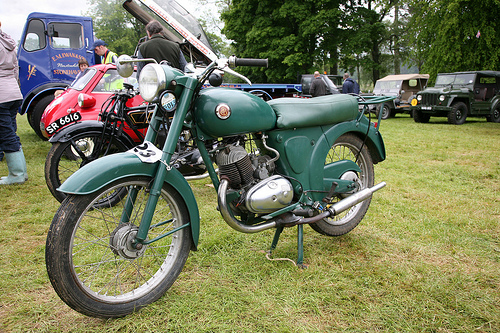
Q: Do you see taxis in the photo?
A: Yes, there is a taxi.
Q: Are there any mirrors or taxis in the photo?
A: Yes, there is a taxi.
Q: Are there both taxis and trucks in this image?
A: Yes, there are both a taxi and trucks.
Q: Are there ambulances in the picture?
A: No, there are no ambulances.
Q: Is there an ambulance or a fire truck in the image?
A: No, there are no ambulances or fire trucks.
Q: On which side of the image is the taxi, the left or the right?
A: The taxi is on the right of the image.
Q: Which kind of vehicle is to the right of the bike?
A: The vehicle is a taxi.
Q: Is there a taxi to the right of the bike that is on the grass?
A: Yes, there is a taxi to the right of the bike.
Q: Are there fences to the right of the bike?
A: No, there is a taxi to the right of the bike.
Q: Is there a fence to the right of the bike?
A: No, there is a taxi to the right of the bike.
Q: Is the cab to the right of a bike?
A: Yes, the cab is to the right of a bike.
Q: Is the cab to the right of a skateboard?
A: No, the cab is to the right of a bike.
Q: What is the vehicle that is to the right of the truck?
A: The vehicle is a taxi.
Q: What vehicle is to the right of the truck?
A: The vehicle is a taxi.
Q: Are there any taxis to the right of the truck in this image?
A: Yes, there is a taxi to the right of the truck.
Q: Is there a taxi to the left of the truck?
A: No, the taxi is to the right of the truck.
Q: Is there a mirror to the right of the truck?
A: No, there is a taxi to the right of the truck.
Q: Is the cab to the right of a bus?
A: No, the cab is to the right of the truck.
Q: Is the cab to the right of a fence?
A: No, the cab is to the right of the jeep.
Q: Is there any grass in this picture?
A: Yes, there is grass.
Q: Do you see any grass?
A: Yes, there is grass.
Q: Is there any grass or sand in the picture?
A: Yes, there is grass.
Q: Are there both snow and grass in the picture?
A: No, there is grass but no snow.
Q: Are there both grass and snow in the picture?
A: No, there is grass but no snow.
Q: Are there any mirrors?
A: No, there are no mirrors.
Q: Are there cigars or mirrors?
A: No, there are no mirrors or cigars.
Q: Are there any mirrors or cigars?
A: No, there are no mirrors or cigars.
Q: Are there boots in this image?
A: Yes, there are boots.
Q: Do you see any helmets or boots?
A: Yes, there are boots.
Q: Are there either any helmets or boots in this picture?
A: Yes, there are boots.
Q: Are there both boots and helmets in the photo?
A: No, there are boots but no helmets.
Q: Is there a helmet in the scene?
A: No, there are no helmets.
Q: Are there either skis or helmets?
A: No, there are no helmets or skis.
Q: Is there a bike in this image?
A: Yes, there is a bike.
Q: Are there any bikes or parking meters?
A: Yes, there is a bike.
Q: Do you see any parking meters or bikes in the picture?
A: Yes, there is a bike.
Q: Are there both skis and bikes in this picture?
A: No, there is a bike but no skis.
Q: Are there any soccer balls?
A: No, there are no soccer balls.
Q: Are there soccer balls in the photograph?
A: No, there are no soccer balls.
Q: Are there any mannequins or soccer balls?
A: No, there are no soccer balls or mannequins.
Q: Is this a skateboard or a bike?
A: This is a bike.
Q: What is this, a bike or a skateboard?
A: This is a bike.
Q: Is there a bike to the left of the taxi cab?
A: Yes, there is a bike to the left of the taxi cab.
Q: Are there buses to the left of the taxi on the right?
A: No, there is a bike to the left of the cab.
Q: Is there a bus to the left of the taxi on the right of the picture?
A: No, there is a bike to the left of the cab.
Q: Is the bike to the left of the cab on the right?
A: Yes, the bike is to the left of the cab.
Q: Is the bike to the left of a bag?
A: No, the bike is to the left of the cab.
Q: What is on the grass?
A: The bike is on the grass.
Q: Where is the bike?
A: The bike is on the grass.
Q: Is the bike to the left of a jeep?
A: Yes, the bike is to the left of a jeep.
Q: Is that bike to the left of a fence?
A: No, the bike is to the left of a jeep.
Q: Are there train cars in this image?
A: No, there are no train cars.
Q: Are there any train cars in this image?
A: No, there are no train cars.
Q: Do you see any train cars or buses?
A: No, there are no train cars or buses.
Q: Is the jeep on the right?
A: Yes, the jeep is on the right of the image.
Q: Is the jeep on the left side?
A: No, the jeep is on the right of the image.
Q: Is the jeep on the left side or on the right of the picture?
A: The jeep is on the right of the image.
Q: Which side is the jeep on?
A: The jeep is on the right of the image.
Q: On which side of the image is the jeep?
A: The jeep is on the right of the image.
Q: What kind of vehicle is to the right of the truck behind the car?
A: The vehicle is a jeep.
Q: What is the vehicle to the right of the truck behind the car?
A: The vehicle is a jeep.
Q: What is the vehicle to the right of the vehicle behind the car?
A: The vehicle is a jeep.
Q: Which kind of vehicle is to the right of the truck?
A: The vehicle is a jeep.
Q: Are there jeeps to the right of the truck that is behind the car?
A: Yes, there is a jeep to the right of the truck.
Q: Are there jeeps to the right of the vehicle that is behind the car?
A: Yes, there is a jeep to the right of the truck.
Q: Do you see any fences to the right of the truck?
A: No, there is a jeep to the right of the truck.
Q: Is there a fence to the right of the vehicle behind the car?
A: No, there is a jeep to the right of the truck.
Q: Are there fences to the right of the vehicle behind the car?
A: No, there is a jeep to the right of the truck.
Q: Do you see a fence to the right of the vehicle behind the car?
A: No, there is a jeep to the right of the truck.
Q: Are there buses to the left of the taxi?
A: No, there is a jeep to the left of the taxi.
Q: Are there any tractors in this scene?
A: No, there are no tractors.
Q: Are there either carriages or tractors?
A: No, there are no tractors or carriages.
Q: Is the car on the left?
A: Yes, the car is on the left of the image.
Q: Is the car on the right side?
A: No, the car is on the left of the image.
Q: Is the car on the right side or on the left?
A: The car is on the left of the image.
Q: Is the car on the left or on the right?
A: The car is on the left of the image.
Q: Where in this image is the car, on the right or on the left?
A: The car is on the left of the image.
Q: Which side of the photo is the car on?
A: The car is on the left of the image.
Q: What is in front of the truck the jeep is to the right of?
A: The car is in front of the truck.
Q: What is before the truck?
A: The car is in front of the truck.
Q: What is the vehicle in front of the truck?
A: The vehicle is a car.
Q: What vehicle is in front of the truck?
A: The vehicle is a car.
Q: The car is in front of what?
A: The car is in front of the truck.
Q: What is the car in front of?
A: The car is in front of the truck.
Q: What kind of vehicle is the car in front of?
A: The car is in front of the truck.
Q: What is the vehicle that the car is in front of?
A: The vehicle is a truck.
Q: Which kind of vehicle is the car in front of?
A: The car is in front of the truck.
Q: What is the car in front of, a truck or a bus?
A: The car is in front of a truck.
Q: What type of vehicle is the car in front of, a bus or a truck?
A: The car is in front of a truck.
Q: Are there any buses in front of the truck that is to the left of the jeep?
A: No, there is a car in front of the truck.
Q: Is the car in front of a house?
A: No, the car is in front of the truck.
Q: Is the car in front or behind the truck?
A: The car is in front of the truck.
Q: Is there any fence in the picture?
A: No, there are no fences.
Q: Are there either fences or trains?
A: No, there are no fences or trains.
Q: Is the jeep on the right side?
A: Yes, the jeep is on the right of the image.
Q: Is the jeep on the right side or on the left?
A: The jeep is on the right of the image.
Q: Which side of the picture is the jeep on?
A: The jeep is on the right of the image.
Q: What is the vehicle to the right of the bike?
A: The vehicle is a jeep.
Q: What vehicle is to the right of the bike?
A: The vehicle is a jeep.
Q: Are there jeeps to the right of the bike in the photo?
A: Yes, there is a jeep to the right of the bike.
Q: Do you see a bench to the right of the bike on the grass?
A: No, there is a jeep to the right of the bike.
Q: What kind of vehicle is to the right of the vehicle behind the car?
A: The vehicle is a jeep.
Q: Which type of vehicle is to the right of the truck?
A: The vehicle is a jeep.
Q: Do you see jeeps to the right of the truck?
A: Yes, there is a jeep to the right of the truck.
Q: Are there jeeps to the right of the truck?
A: Yes, there is a jeep to the right of the truck.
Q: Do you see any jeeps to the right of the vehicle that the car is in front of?
A: Yes, there is a jeep to the right of the truck.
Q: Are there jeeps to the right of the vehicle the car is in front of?
A: Yes, there is a jeep to the right of the truck.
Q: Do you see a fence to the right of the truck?
A: No, there is a jeep to the right of the truck.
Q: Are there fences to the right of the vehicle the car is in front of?
A: No, there is a jeep to the right of the truck.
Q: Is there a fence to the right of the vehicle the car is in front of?
A: No, there is a jeep to the right of the truck.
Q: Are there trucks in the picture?
A: Yes, there is a truck.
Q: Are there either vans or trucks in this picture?
A: Yes, there is a truck.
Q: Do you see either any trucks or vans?
A: Yes, there is a truck.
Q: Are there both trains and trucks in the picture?
A: No, there is a truck but no trains.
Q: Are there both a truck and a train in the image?
A: No, there is a truck but no trains.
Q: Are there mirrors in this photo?
A: No, there are no mirrors.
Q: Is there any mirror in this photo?
A: No, there are no mirrors.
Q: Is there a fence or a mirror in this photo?
A: No, there are no mirrors or fences.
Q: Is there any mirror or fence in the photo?
A: No, there are no mirrors or fences.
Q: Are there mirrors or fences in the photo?
A: No, there are no mirrors or fences.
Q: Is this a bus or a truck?
A: This is a truck.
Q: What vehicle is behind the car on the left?
A: The vehicle is a truck.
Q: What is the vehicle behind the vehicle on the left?
A: The vehicle is a truck.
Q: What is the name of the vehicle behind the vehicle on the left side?
A: The vehicle is a truck.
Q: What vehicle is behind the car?
A: The vehicle is a truck.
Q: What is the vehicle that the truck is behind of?
A: The vehicle is a car.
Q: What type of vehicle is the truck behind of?
A: The truck is behind the car.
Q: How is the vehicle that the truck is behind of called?
A: The vehicle is a car.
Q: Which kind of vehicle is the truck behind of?
A: The truck is behind the car.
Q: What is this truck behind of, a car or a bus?
A: The truck is behind a car.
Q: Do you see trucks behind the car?
A: Yes, there is a truck behind the car.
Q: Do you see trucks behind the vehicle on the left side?
A: Yes, there is a truck behind the car.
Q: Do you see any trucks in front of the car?
A: No, the truck is behind the car.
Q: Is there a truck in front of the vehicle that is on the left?
A: No, the truck is behind the car.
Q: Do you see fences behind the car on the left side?
A: No, there is a truck behind the car.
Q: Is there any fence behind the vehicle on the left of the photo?
A: No, there is a truck behind the car.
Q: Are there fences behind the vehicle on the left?
A: No, there is a truck behind the car.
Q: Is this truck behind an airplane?
A: No, the truck is behind the car.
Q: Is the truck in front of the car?
A: No, the truck is behind the car.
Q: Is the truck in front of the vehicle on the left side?
A: No, the truck is behind the car.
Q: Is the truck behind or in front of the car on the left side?
A: The truck is behind the car.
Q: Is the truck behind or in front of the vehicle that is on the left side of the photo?
A: The truck is behind the car.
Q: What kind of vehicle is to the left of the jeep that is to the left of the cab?
A: The vehicle is a truck.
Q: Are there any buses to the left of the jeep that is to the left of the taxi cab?
A: No, there is a truck to the left of the jeep.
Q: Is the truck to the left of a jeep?
A: Yes, the truck is to the left of a jeep.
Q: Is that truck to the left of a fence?
A: No, the truck is to the left of a jeep.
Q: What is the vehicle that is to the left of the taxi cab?
A: The vehicle is a truck.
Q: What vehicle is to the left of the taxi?
A: The vehicle is a truck.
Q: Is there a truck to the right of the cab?
A: No, the truck is to the left of the cab.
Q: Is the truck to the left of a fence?
A: No, the truck is to the left of the taxi.